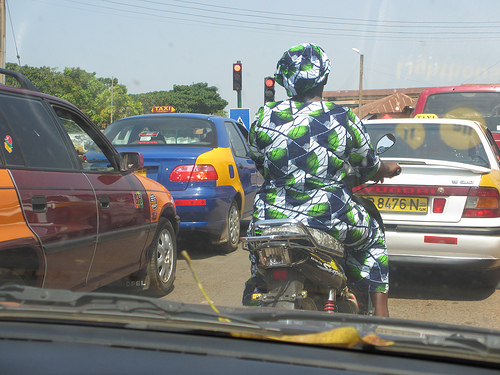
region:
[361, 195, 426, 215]
License plate on car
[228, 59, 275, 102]
Traffic control signals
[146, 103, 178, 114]
Taxi cab identification sign on car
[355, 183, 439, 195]
Manufacturer name on car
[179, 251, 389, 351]
Dead leaf on windshield of car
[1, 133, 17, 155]
Decal on window of car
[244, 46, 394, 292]
Colorful outfit on motorcyclist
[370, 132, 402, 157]
Rearview mirror on motorcycle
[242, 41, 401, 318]
Woman riding motorbike in heavy traffic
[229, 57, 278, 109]
two traffic signals showing red lights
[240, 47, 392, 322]
person sitting on moped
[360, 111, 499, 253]
white car in front of moped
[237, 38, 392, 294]
blue, green, and white outfit of moped rider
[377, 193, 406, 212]
black numbers on a yellow background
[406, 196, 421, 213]
black letter on yellow license plate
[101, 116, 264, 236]
blue car with yellow spot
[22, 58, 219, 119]
treetops peaking above the cars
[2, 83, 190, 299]
blue colored car with orange spots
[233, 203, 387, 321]
silver moped person is sitting on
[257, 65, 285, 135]
a red traffic light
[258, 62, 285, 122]
a semaphore turned red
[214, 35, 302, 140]
yellow and red traffic lights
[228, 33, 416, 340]
person riding a motorcycle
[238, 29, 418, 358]
a person on a motorbike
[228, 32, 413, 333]
person riding a motorbike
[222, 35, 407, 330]
person riding a motorcycle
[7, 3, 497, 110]
blue of daytime sky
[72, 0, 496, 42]
black wires in sky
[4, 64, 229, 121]
green leaves on trees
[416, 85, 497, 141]
window on red truck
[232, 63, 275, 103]
glowing circles on traffic lights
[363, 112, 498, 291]
back of taxi cab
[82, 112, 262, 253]
blue and yellow vehicle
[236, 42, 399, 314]
woman sitting on motorbike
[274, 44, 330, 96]
cloth covering woman's head